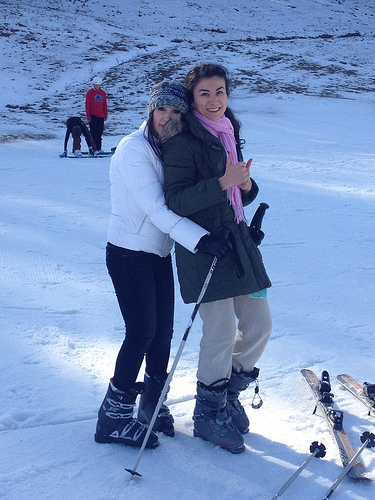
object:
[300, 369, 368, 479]
skis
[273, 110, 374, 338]
snow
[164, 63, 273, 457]
women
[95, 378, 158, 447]
boots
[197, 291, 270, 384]
pants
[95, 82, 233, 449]
woman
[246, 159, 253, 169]
thumbs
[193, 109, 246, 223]
scarf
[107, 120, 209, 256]
jacket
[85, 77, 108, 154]
person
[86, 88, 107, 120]
shirt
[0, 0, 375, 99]
ground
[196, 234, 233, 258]
gloves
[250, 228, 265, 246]
glove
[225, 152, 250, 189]
hand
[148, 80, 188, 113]
hat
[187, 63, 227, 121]
head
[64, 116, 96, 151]
boy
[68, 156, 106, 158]
snowboard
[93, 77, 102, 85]
helmet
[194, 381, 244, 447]
feet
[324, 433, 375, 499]
poles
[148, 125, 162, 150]
neck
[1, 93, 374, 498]
ground